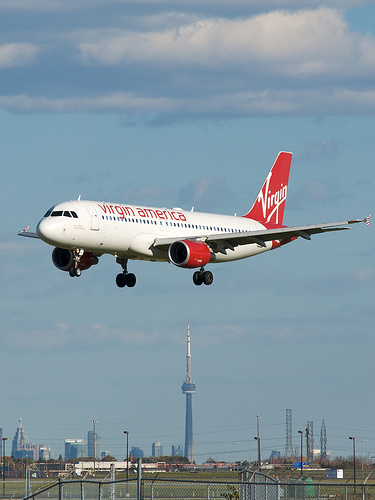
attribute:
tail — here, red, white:
[244, 152, 289, 224]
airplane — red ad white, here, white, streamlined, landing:
[18, 150, 370, 288]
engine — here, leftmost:
[165, 241, 211, 269]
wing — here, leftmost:
[155, 216, 368, 257]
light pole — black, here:
[345, 434, 357, 486]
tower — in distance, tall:
[182, 323, 197, 458]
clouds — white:
[4, 0, 374, 121]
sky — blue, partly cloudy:
[0, 0, 371, 459]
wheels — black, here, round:
[69, 262, 218, 288]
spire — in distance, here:
[181, 322, 197, 453]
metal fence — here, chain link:
[19, 465, 371, 496]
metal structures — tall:
[283, 407, 328, 463]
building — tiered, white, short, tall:
[11, 417, 28, 456]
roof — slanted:
[13, 419, 27, 438]